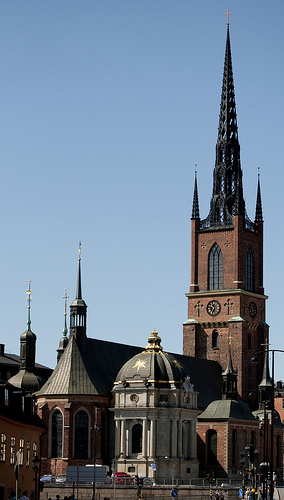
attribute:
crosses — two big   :
[193, 295, 241, 320]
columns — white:
[143, 416, 153, 457]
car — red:
[109, 469, 135, 485]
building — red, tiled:
[1, 8, 283, 499]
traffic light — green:
[210, 475, 216, 481]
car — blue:
[39, 472, 53, 484]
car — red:
[105, 469, 133, 485]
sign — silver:
[64, 463, 107, 485]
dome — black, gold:
[112, 327, 198, 391]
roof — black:
[29, 334, 243, 398]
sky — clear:
[50, 97, 124, 203]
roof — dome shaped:
[98, 306, 212, 452]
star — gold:
[126, 356, 150, 372]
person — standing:
[231, 456, 273, 494]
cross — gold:
[220, 8, 232, 27]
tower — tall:
[186, 16, 272, 391]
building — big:
[0, 283, 282, 473]